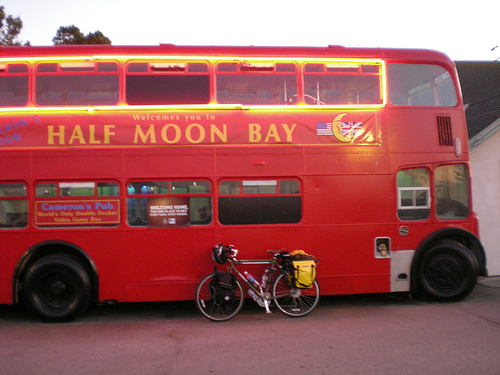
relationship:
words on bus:
[42, 121, 298, 142] [8, 27, 498, 339]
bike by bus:
[197, 238, 347, 335] [12, 42, 495, 289]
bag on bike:
[282, 250, 321, 289] [192, 234, 329, 322]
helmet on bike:
[210, 244, 239, 262] [194, 244, 318, 320]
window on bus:
[128, 174, 220, 234] [2, 45, 484, 321]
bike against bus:
[196, 243, 321, 322] [2, 45, 484, 321]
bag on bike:
[287, 244, 322, 293] [196, 243, 321, 322]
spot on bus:
[376, 240, 387, 257] [2, 45, 484, 321]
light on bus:
[0, 55, 389, 114] [4, 31, 484, 368]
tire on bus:
[25, 260, 92, 314] [2, 45, 484, 321]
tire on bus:
[415, 236, 475, 306] [2, 45, 484, 321]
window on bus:
[215, 175, 304, 225] [2, 45, 484, 321]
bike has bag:
[196, 243, 321, 322] [280, 247, 320, 289]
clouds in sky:
[0, 0, 498, 62] [0, 0, 500, 62]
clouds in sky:
[0, 0, 498, 62] [0, 2, 496, 57]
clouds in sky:
[0, 0, 498, 62] [6, 2, 498, 57]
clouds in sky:
[0, 0, 498, 62] [203, 1, 477, 41]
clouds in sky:
[0, 0, 498, 62] [370, 7, 454, 40]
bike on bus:
[196, 243, 321, 322] [2, 45, 484, 321]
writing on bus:
[43, 122, 296, 145] [2, 45, 484, 321]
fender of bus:
[413, 225, 488, 277] [2, 45, 484, 321]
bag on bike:
[282, 250, 321, 289] [196, 243, 321, 322]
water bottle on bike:
[242, 264, 262, 293] [189, 228, 329, 326]